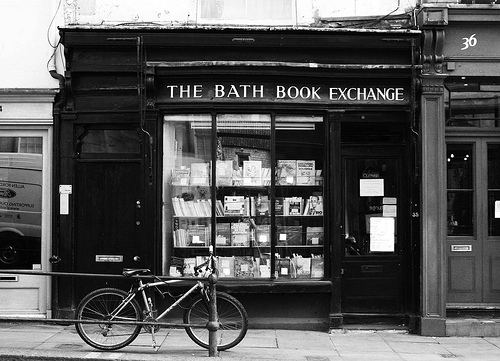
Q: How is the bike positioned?
A: Parked.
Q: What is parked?
A: The bike.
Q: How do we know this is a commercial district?
A: A retail venue is shown.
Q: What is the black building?
A: A bookstore.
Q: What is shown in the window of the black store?
A: Shelves with books on them.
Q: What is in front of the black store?
A: A sidewalk and a railing with a bike next to it.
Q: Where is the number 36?
A: On the building to the right of the black store.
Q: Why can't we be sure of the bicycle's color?
A: The photo is black and white.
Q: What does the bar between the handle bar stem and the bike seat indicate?
A: The bike is meant for male riders.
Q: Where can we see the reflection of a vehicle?
A: In the plate glass of a store to the left of the Book Exchange.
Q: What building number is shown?
A: 36.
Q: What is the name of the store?
A: The Bath Book Exchange.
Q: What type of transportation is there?
A: Bicycle.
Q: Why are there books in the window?
A: Book store.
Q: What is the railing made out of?
A: Metal.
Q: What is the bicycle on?
A: The sidewalk.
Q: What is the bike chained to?
A: A metal railing.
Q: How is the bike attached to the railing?
A: With a chain.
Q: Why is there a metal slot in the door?
A: For mail.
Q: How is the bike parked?
A: Upright against fence.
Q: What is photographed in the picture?
A: A bookstore.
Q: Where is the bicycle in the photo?
A: The sidewalk.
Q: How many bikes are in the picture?
A: One.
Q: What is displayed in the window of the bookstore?
A: Books.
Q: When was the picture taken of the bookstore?
A: Daytime.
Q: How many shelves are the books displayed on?
A: Four.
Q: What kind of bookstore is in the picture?
A: Exchange.